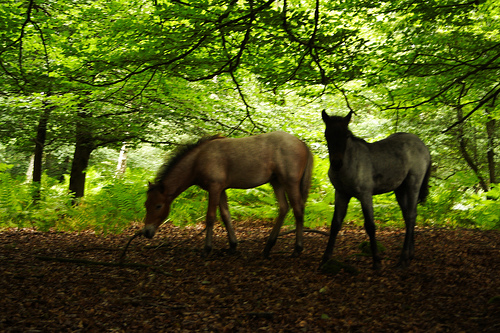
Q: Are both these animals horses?
A: Yes, all the animals are horses.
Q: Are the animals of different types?
A: No, all the animals are horses.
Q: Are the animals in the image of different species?
A: No, all the animals are horses.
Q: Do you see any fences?
A: No, there are no fences.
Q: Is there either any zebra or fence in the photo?
A: No, there are no fences or zebras.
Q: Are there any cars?
A: No, there are no cars.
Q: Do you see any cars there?
A: No, there are no cars.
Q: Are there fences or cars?
A: No, there are no cars or fences.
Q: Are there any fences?
A: No, there are no fences.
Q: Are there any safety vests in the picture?
A: No, there are no safety vests.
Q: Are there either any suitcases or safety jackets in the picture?
A: No, there are no safety jackets or suitcases.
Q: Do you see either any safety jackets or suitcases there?
A: No, there are no safety jackets or suitcases.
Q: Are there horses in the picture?
A: Yes, there is a horse.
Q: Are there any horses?
A: Yes, there is a horse.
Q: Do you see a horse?
A: Yes, there is a horse.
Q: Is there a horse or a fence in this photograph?
A: Yes, there is a horse.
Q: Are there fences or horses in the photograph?
A: Yes, there is a horse.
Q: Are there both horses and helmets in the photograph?
A: No, there is a horse but no helmets.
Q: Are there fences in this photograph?
A: No, there are no fences.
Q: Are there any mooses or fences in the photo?
A: No, there are no fences or mooses.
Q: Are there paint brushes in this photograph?
A: No, there are no paint brushes.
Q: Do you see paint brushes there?
A: No, there are no paint brushes.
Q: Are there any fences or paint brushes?
A: No, there are no paint brushes or fences.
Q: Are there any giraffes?
A: No, there are no giraffes.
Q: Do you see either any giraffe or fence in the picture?
A: No, there are no giraffes or fences.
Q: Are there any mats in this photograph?
A: No, there are no mats.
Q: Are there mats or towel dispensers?
A: No, there are no mats or towel dispensers.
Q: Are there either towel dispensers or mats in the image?
A: No, there are no mats or towel dispensers.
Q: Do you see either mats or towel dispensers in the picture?
A: No, there are no mats or towel dispensers.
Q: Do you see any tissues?
A: No, there are no tissues.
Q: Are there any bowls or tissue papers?
A: No, there are no tissue papers or bowls.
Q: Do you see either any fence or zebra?
A: No, there are no fences or zebras.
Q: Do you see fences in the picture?
A: No, there are no fences.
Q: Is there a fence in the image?
A: No, there are no fences.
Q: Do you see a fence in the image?
A: No, there are no fences.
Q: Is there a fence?
A: No, there are no fences.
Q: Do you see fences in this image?
A: No, there are no fences.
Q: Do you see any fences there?
A: No, there are no fences.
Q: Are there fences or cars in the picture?
A: No, there are no fences or cars.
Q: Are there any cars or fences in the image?
A: No, there are no fences or cars.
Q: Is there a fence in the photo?
A: No, there are no fences.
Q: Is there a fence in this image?
A: No, there are no fences.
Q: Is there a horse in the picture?
A: Yes, there is a horse.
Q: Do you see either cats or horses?
A: Yes, there is a horse.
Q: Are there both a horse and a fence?
A: No, there is a horse but no fences.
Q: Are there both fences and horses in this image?
A: No, there is a horse but no fences.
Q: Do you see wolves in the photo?
A: No, there are no wolves.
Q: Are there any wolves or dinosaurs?
A: No, there are no wolves or dinosaurs.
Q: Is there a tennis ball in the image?
A: No, there are no tennis balls.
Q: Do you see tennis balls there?
A: No, there are no tennis balls.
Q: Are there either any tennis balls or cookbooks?
A: No, there are no tennis balls or cookbooks.